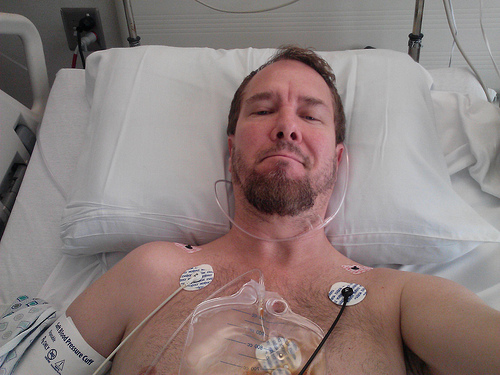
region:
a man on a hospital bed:
[32, 44, 490, 365]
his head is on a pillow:
[69, 34, 492, 247]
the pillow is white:
[75, 44, 497, 266]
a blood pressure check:
[10, 309, 100, 374]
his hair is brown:
[232, 38, 370, 130]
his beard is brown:
[221, 147, 336, 218]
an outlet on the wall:
[55, 0, 107, 64]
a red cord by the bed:
[67, 50, 88, 72]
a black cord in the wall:
[62, 9, 97, 70]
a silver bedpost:
[400, 0, 437, 75]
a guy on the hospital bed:
[18, 37, 428, 364]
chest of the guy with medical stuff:
[132, 261, 380, 373]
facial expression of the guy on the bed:
[225, 40, 341, 221]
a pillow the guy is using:
[56, 35, 499, 264]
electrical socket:
[60, 5, 104, 54]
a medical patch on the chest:
[328, 280, 367, 304]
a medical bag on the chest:
[172, 284, 332, 372]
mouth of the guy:
[253, 148, 308, 170]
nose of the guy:
[270, 105, 302, 146]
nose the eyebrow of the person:
[241, 83, 336, 124]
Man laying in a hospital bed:
[26, 43, 491, 365]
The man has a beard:
[228, 169, 351, 211]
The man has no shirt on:
[89, 230, 431, 373]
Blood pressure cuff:
[19, 305, 108, 372]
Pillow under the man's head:
[74, 45, 456, 244]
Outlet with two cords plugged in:
[46, 7, 110, 64]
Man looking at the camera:
[235, 59, 339, 209]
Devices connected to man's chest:
[81, 254, 376, 374]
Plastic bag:
[186, 276, 326, 372]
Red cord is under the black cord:
[66, 34, 108, 68]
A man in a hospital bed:
[11, 40, 497, 372]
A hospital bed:
[0, 11, 496, 366]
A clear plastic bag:
[180, 281, 325, 371]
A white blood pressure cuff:
[15, 310, 110, 370]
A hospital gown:
[0, 291, 65, 371]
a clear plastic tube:
[211, 140, 356, 242]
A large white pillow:
[56, 45, 496, 265]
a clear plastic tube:
[141, 265, 268, 374]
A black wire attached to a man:
[296, 285, 353, 373]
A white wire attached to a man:
[92, 273, 199, 373]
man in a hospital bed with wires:
[25, 27, 475, 347]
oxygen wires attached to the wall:
[60, 5, 102, 66]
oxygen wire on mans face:
[200, 175, 345, 245]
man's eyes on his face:
[247, 96, 327, 123]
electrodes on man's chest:
[317, 261, 377, 316]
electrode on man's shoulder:
[330, 245, 371, 275]